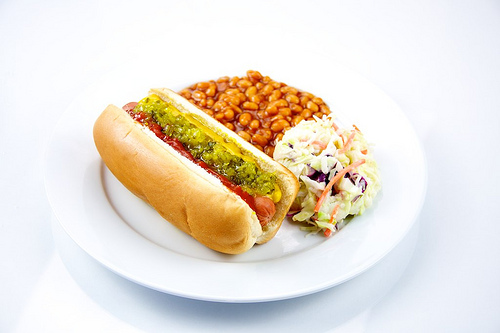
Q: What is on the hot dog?
A: Relish, ketchup and mustard.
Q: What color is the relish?
A: Green.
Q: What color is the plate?
A: White.